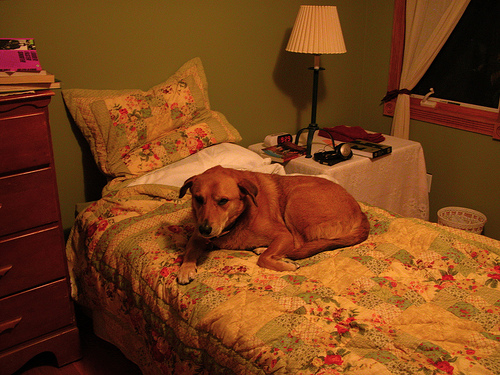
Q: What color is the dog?
A: Brown.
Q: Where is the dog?
A: On the bed.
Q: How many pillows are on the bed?
A: Two.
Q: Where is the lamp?
A: On the nightstand.